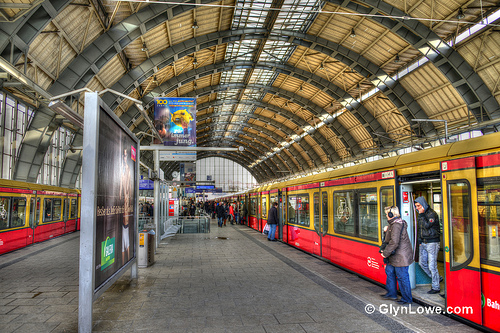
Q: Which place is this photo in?
A: It is at the train station.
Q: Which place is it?
A: It is a train station.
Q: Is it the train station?
A: Yes, it is the train station.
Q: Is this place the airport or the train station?
A: It is the train station.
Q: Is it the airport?
A: No, it is the train station.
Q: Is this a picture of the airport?
A: No, the picture is showing the train station.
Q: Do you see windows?
A: Yes, there are windows.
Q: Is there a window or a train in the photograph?
A: Yes, there are windows.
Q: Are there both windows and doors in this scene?
A: Yes, there are both windows and a door.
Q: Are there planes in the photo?
A: No, there are no planes.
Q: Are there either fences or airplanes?
A: No, there are no airplanes or fences.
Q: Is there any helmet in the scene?
A: No, there are no helmets.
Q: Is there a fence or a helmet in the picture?
A: No, there are no helmets or fences.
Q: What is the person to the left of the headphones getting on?
A: The person is getting on the train.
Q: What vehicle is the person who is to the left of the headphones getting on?
A: The person is getting on the train.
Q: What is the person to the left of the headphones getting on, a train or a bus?
A: The person is getting on a train.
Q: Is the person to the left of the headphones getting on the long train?
A: Yes, the person is getting on the train.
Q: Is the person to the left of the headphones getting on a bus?
A: No, the person is getting on the train.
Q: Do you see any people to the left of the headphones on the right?
A: Yes, there is a person to the left of the headphones.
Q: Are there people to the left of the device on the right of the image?
A: Yes, there is a person to the left of the headphones.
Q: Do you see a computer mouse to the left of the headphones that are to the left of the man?
A: No, there is a person to the left of the headphones.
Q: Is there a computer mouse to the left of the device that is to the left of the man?
A: No, there is a person to the left of the headphones.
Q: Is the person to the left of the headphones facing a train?
A: Yes, the person is facing a train.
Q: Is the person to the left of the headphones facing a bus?
A: No, the person is facing a train.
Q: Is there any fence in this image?
A: No, there are no fences.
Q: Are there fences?
A: No, there are no fences.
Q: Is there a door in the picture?
A: Yes, there is a door.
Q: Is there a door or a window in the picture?
A: Yes, there is a door.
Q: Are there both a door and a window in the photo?
A: Yes, there are both a door and a window.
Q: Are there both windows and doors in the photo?
A: Yes, there are both a door and a window.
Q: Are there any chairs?
A: No, there are no chairs.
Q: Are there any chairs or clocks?
A: No, there are no chairs or clocks.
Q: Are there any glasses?
A: No, there are no glasses.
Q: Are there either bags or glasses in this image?
A: No, there are no glasses or bags.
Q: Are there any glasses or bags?
A: No, there are no glasses or bags.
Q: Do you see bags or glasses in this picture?
A: No, there are no glasses or bags.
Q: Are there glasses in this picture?
A: No, there are no glasses.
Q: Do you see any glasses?
A: No, there are no glasses.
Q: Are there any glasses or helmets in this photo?
A: No, there are no glasses or helmets.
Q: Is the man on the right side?
A: Yes, the man is on the right of the image.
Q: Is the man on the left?
A: No, the man is on the right of the image.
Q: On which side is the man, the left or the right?
A: The man is on the right of the image.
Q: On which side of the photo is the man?
A: The man is on the right of the image.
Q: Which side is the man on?
A: The man is on the right of the image.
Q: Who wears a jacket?
A: The man wears a jacket.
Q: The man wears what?
A: The man wears a jacket.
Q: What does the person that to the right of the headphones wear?
A: The man wears a jacket.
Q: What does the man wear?
A: The man wears a jacket.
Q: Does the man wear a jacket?
A: Yes, the man wears a jacket.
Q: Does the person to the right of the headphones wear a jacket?
A: Yes, the man wears a jacket.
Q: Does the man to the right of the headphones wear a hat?
A: No, the man wears a jacket.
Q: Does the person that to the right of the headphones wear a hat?
A: No, the man wears a jacket.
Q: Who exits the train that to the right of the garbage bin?
A: The man exits the train.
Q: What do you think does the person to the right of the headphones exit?
A: The man exits the train.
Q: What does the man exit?
A: The man exits the train.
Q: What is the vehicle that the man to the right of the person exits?
A: The vehicle is a train.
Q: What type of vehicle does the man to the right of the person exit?
A: The man exits the train.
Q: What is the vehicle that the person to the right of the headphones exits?
A: The vehicle is a train.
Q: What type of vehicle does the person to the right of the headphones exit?
A: The man exits the train.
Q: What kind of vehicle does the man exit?
A: The man exits the train.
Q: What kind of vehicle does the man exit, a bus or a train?
A: The man exits a train.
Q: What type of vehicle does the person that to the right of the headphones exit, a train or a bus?
A: The man exits a train.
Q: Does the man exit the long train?
A: Yes, the man exits the train.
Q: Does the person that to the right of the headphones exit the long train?
A: Yes, the man exits the train.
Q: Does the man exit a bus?
A: No, the man exits the train.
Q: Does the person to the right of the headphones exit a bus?
A: No, the man exits the train.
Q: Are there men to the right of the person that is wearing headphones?
A: Yes, there is a man to the right of the person.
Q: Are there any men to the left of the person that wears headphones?
A: No, the man is to the right of the person.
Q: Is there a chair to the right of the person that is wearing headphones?
A: No, there is a man to the right of the person.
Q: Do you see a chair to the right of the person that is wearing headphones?
A: No, there is a man to the right of the person.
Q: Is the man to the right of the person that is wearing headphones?
A: Yes, the man is to the right of the person.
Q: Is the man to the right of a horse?
A: No, the man is to the right of the person.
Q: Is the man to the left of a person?
A: No, the man is to the right of a person.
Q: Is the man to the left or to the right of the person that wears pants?
A: The man is to the right of the person.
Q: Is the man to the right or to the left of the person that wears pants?
A: The man is to the right of the person.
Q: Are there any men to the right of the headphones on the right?
A: Yes, there is a man to the right of the headphones.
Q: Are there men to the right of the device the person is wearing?
A: Yes, there is a man to the right of the headphones.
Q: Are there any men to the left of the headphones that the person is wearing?
A: No, the man is to the right of the headphones.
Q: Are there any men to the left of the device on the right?
A: No, the man is to the right of the headphones.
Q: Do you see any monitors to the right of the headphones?
A: No, there is a man to the right of the headphones.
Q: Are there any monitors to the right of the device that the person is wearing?
A: No, there is a man to the right of the headphones.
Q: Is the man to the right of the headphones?
A: Yes, the man is to the right of the headphones.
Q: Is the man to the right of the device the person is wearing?
A: Yes, the man is to the right of the headphones.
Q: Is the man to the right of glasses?
A: No, the man is to the right of the headphones.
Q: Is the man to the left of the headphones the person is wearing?
A: No, the man is to the right of the headphones.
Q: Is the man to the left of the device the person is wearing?
A: No, the man is to the right of the headphones.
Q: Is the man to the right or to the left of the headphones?
A: The man is to the right of the headphones.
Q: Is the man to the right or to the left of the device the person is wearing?
A: The man is to the right of the headphones.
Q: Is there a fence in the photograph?
A: No, there are no fences.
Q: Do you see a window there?
A: Yes, there are windows.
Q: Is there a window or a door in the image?
A: Yes, there are windows.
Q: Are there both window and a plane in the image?
A: No, there are windows but no airplanes.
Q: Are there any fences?
A: No, there are no fences.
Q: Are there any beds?
A: No, there are no beds.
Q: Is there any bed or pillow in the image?
A: No, there are no beds or pillows.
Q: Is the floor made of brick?
A: Yes, the floor is made of brick.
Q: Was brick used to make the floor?
A: Yes, the floor is made of brick.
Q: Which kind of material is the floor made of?
A: The floor is made of brick.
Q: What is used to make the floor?
A: The floor is made of brick.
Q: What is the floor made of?
A: The floor is made of brick.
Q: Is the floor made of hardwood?
A: No, the floor is made of brick.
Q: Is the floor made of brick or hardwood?
A: The floor is made of brick.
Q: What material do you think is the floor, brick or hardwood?
A: The floor is made of brick.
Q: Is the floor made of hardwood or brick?
A: The floor is made of brick.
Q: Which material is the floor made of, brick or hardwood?
A: The floor is made of brick.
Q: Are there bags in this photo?
A: No, there are no bags.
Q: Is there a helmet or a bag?
A: No, there are no bags or helmets.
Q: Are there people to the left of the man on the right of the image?
A: Yes, there is a person to the left of the man.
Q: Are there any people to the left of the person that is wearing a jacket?
A: Yes, there is a person to the left of the man.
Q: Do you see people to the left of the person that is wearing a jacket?
A: Yes, there is a person to the left of the man.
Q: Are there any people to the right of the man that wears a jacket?
A: No, the person is to the left of the man.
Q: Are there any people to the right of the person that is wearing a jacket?
A: No, the person is to the left of the man.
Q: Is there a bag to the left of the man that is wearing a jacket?
A: No, there is a person to the left of the man.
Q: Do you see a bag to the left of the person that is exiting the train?
A: No, there is a person to the left of the man.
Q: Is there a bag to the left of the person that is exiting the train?
A: No, there is a person to the left of the man.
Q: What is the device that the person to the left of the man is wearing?
A: The device is headphones.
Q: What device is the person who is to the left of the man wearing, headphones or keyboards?
A: The person is wearing headphones.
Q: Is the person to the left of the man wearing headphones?
A: Yes, the person is wearing headphones.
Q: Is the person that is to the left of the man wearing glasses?
A: No, the person is wearing headphones.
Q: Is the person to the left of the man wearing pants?
A: Yes, the person is wearing pants.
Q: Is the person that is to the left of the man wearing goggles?
A: No, the person is wearing pants.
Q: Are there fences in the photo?
A: No, there are no fences.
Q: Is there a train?
A: Yes, there is a train.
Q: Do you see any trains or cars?
A: Yes, there is a train.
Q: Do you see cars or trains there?
A: Yes, there is a train.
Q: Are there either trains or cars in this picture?
A: Yes, there is a train.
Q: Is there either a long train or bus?
A: Yes, there is a long train.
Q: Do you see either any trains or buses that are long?
A: Yes, the train is long.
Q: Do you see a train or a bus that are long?
A: Yes, the train is long.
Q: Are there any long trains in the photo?
A: Yes, there is a long train.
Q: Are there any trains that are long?
A: Yes, there is a train that is long.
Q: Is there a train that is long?
A: Yes, there is a train that is long.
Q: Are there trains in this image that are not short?
A: Yes, there is a long train.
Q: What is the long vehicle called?
A: The vehicle is a train.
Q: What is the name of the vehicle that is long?
A: The vehicle is a train.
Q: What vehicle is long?
A: The vehicle is a train.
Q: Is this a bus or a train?
A: This is a train.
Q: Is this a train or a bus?
A: This is a train.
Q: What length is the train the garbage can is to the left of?
A: The train is long.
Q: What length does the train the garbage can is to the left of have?
A: The train has long length.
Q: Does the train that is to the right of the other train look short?
A: No, the train is long.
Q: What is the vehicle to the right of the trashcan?
A: The vehicle is a train.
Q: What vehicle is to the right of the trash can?
A: The vehicle is a train.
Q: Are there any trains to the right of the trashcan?
A: Yes, there is a train to the right of the trashcan.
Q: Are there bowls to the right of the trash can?
A: No, there is a train to the right of the trash can.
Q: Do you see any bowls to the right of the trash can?
A: No, there is a train to the right of the trash can.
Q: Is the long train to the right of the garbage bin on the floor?
A: Yes, the train is to the right of the garbage can.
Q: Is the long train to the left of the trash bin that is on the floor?
A: No, the train is to the right of the trash can.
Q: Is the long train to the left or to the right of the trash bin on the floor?
A: The train is to the right of the trash can.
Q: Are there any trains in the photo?
A: Yes, there is a train.